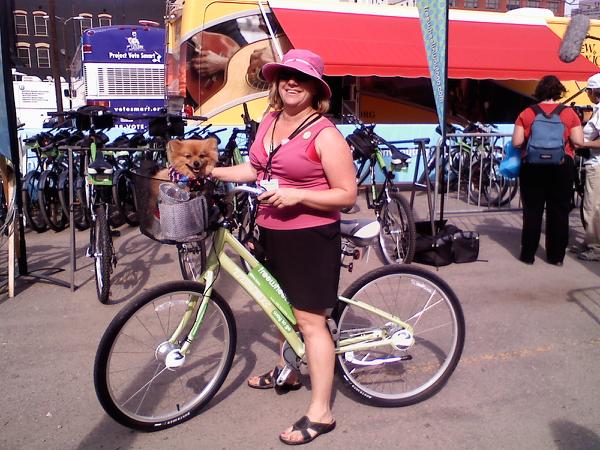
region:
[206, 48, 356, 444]
Lady in the pink shirt on a bike.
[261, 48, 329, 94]
Carnelian pink hat atop the ladies head.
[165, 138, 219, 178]
Brown dog riding on the lady's bike.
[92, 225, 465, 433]
The green-yellow bike the lady is on.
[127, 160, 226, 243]
Bicycle basket the dog sits in.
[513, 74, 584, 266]
Cyclist with a red shirt and blue a backpack.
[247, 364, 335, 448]
Brown, strapped sandals the lady is wearing.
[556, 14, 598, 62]
Sound boom in the background.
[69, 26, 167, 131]
Blue bus behind the bike rack.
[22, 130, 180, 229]
Miscellaneous bike rack.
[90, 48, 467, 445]
A lady on a bike.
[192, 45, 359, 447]
A lady wearing a pink top.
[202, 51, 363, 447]
A lady wearing a pink hat.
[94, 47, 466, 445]
A lady with her dog on a bike.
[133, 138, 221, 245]
A brown dog in a basket.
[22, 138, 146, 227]
A row of parked bikes.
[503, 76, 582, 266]
A lady with a back pack .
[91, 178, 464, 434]
A lime green bike.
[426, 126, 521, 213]
A gray bike rack for bikes.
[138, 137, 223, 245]
dog in a basket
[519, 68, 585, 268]
person wearing a back pack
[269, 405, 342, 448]
brown sandal on the foot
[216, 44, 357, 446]
woman with a pink hat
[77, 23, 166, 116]
grate on the back of the bus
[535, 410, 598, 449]
shadow on the ground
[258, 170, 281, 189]
name tag on the lady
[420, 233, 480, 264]
luggage on the ground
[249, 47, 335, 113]
a woman wearing a pink hat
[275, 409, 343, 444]
A black sandal on a foot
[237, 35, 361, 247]
A woman wearing a pink tank top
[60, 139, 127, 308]
a bicycle in a parking spot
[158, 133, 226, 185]
the head of a dog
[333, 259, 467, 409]
the back wheel of the bicycle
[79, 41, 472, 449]
Lady on a bicycle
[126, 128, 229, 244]
Dog in the bicycle basket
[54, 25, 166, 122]
Blue and white bus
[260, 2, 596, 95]
Red awning on the truck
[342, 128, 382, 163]
Black bag on the bike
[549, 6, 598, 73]
news mic in the air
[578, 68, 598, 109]
Person wearing a white hat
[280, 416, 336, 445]
the sandal is black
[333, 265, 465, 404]
the tire is black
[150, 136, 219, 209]
the dog is brown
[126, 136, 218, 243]
the dog is in the basket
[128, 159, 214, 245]
the basket is black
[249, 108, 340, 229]
the top is pink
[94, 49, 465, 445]
the woman standing above the bike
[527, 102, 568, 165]
the backpack is blue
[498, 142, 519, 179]
the bag is blue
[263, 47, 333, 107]
a woman wearing a pink hat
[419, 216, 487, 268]
two black bags on the ground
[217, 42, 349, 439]
a woman on a bicycle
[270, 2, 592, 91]
a red awning on a bus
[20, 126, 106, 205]
a row of parked bicycles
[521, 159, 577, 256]
a man wearing black pants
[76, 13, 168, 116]
a purple bus with white letters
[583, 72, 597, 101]
a man wearing a white hat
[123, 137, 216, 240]
a dog sitting in a bike basket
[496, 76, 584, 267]
a person wearing a blue backpack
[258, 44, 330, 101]
pink sun hat on a womans head